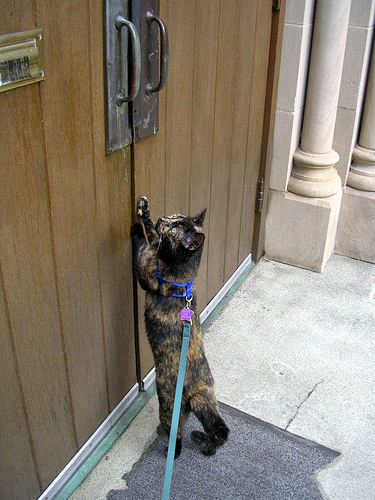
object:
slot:
[1, 23, 46, 93]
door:
[1, 1, 288, 499]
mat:
[104, 402, 342, 500]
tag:
[178, 306, 194, 323]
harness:
[154, 273, 195, 299]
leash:
[158, 320, 192, 500]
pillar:
[285, 1, 353, 198]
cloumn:
[348, 27, 374, 192]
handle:
[114, 17, 141, 107]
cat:
[130, 191, 230, 459]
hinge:
[255, 178, 265, 215]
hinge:
[272, 1, 282, 13]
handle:
[143, 10, 169, 100]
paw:
[137, 195, 150, 216]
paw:
[130, 222, 143, 238]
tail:
[191, 392, 230, 448]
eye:
[171, 227, 176, 234]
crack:
[284, 376, 322, 430]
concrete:
[64, 253, 374, 500]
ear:
[181, 229, 206, 251]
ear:
[192, 207, 208, 228]